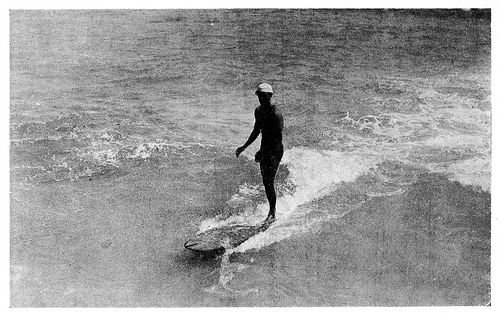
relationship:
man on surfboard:
[234, 81, 287, 224] [184, 216, 258, 257]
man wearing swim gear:
[234, 81, 287, 224] [253, 102, 283, 216]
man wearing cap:
[234, 81, 287, 224] [255, 81, 274, 97]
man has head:
[234, 81, 287, 224] [254, 82, 274, 102]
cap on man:
[254, 81, 272, 93] [234, 81, 287, 224]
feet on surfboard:
[255, 217, 268, 232] [184, 220, 261, 258]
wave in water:
[198, 142, 375, 256] [15, 13, 393, 292]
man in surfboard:
[234, 81, 287, 224] [184, 223, 259, 258]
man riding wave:
[234, 81, 287, 224] [104, 140, 387, 251]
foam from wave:
[286, 143, 421, 204] [104, 140, 387, 251]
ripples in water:
[14, 13, 272, 88] [14, 14, 424, 277]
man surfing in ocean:
[234, 81, 287, 224] [10, 8, 492, 307]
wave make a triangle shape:
[192, 69, 491, 295] [294, 153, 484, 309]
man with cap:
[234, 81, 287, 224] [256, 83, 274, 95]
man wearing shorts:
[234, 81, 287, 224] [258, 142, 284, 168]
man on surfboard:
[234, 81, 287, 224] [186, 225, 261, 252]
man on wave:
[234, 81, 287, 224] [21, 76, 488, 240]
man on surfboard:
[234, 81, 287, 224] [183, 227, 268, 252]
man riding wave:
[236, 83, 290, 220] [16, 86, 499, 281]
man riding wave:
[234, 81, 287, 224] [21, 76, 488, 240]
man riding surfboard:
[234, 81, 287, 224] [186, 226, 257, 253]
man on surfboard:
[234, 81, 287, 224] [186, 226, 257, 253]